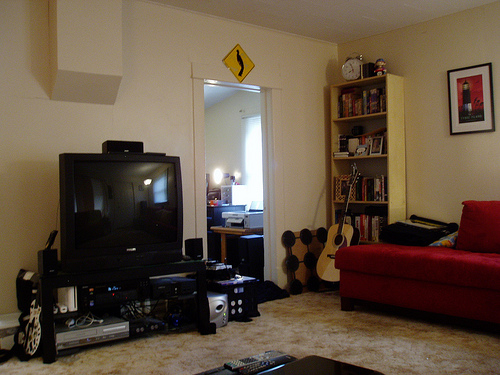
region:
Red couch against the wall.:
[332, 183, 499, 340]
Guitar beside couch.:
[312, 169, 364, 289]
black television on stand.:
[56, 146, 185, 264]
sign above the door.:
[220, 40, 257, 81]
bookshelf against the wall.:
[323, 75, 405, 256]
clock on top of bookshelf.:
[334, 54, 364, 81]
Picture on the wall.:
[441, 63, 498, 135]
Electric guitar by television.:
[15, 226, 56, 356]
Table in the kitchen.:
[210, 220, 261, 266]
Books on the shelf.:
[339, 210, 385, 245]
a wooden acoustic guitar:
[307, 155, 368, 286]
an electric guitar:
[9, 219, 64, 359]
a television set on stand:
[45, 135, 187, 279]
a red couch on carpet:
[332, 172, 499, 330]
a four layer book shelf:
[312, 50, 414, 275]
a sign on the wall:
[210, 37, 265, 84]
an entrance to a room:
[184, 57, 287, 307]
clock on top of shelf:
[336, 43, 373, 83]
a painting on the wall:
[432, 49, 498, 138]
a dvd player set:
[39, 310, 138, 350]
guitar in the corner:
[312, 163, 363, 285]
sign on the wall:
[221, 40, 256, 85]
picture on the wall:
[440, 59, 497, 139]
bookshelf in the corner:
[314, 71, 412, 257]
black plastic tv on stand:
[49, 146, 198, 278]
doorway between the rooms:
[195, 73, 285, 290]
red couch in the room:
[323, 199, 498, 351]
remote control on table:
[226, 355, 285, 373]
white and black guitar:
[13, 226, 68, 364]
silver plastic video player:
[47, 310, 135, 350]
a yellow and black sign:
[220, 32, 258, 84]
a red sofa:
[336, 202, 498, 312]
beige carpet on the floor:
[287, 300, 360, 345]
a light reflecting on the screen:
[134, 172, 154, 193]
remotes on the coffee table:
[221, 349, 293, 371]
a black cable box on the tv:
[94, 135, 153, 156]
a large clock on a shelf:
[329, 48, 360, 86]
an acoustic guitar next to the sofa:
[316, 162, 355, 282]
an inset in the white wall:
[48, 0, 127, 105]